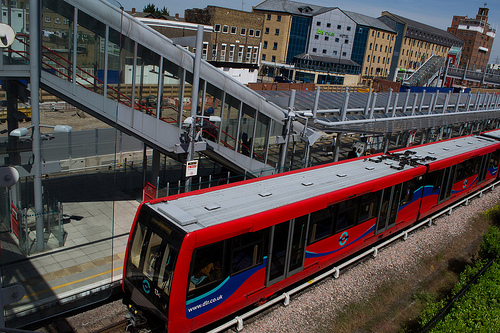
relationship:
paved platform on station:
[16, 119, 496, 321] [20, 11, 482, 327]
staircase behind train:
[30, 1, 284, 179] [121, 130, 498, 332]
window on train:
[126, 221, 183, 293] [121, 130, 498, 332]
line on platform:
[21, 272, 124, 302] [13, 171, 140, 312]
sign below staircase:
[182, 159, 200, 179] [1, 7, 317, 179]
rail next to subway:
[188, 180, 498, 324] [117, 115, 495, 326]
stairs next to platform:
[5, 5, 317, 192] [1, 186, 151, 303]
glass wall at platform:
[1, 1, 113, 324] [1, 1, 133, 304]